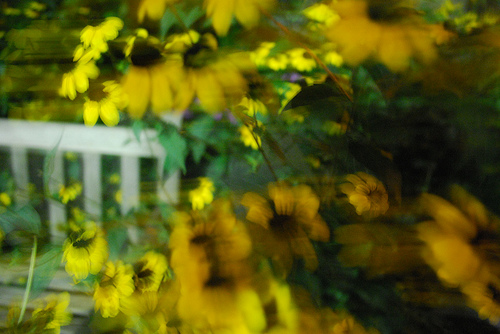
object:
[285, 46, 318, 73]
flower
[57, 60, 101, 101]
flower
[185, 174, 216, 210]
flower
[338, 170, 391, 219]
flower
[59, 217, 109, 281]
flower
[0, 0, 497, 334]
bush